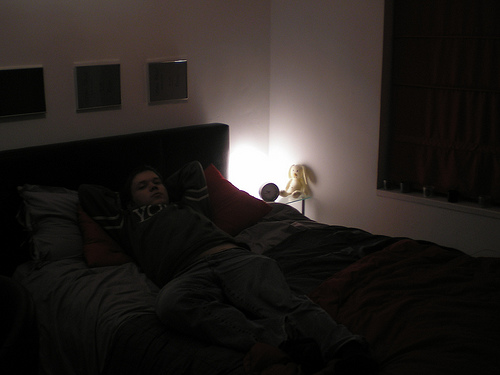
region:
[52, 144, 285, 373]
person laying in bed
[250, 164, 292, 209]
illuminated lamp in bedroom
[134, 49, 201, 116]
photo in frame on wall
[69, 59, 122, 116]
photo in frame on wall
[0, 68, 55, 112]
photo in frame on wall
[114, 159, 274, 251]
red pillow under head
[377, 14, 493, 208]
window on wall of bedroom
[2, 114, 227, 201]
wood backboard of bed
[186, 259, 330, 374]
sweat pants on man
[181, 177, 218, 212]
stripes on man's shirt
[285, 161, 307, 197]
Bunny sitting on nightstand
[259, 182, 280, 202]
Clock sitting on nightstand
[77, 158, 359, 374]
Boy laying on bed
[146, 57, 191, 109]
Small picture hanging above bed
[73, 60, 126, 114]
Middle picture hanging on wall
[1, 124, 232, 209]
Headboard is made of wood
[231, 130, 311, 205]
Light is shining in corner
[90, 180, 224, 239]
Sweater has stripes on sleeves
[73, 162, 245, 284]
Boy is wearing sweater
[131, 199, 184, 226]
Sweater has letters on front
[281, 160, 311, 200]
The rabbit on the side table.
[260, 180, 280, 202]
The clock on the side table.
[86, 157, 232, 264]
The shirt the guy is wearing.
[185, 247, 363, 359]
The pants the guy is wearing.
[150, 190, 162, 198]
The mouth of the man.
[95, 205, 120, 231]
The stripes on the left sleeve of the man's sweater.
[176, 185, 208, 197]
The stripes on the right sleeve of the man's sweater.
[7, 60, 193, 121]
The frames above the headboard of the bed.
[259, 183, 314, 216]
The side table next to the bed.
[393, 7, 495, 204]
The curtain on the window.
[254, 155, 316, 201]
small light on ground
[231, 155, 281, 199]
night light in corner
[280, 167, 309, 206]
stuffed animal in corner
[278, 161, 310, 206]
stuffed rabbit in corner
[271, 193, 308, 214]
small desk in corner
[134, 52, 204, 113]
picture hanging on wall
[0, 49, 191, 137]
pictures on wall hanging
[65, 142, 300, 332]
boy laying on bed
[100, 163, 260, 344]
boy sleeping on bed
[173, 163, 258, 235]
red pillow on bed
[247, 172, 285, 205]
clock on night stand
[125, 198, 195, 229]
white letters on front of man's shirt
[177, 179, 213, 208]
two stripes on sleeve of man's shirt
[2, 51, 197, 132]
three framed pictures on wall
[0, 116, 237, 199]
brown headboard on bed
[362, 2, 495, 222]
window on wall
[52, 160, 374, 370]
man lying on bed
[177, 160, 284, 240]
red pillow at head of bead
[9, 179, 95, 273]
grey pillow at head of bed